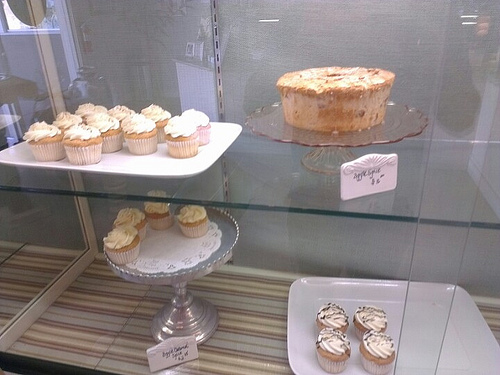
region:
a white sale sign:
[145, 331, 206, 373]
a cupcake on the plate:
[313, 299, 350, 335]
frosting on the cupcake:
[313, 325, 350, 355]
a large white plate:
[282, 267, 499, 373]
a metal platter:
[100, 200, 250, 352]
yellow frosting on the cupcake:
[175, 202, 209, 225]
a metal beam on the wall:
[208, 0, 237, 218]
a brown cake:
[270, 61, 400, 132]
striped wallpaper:
[0, 252, 499, 373]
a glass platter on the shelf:
[241, 97, 430, 179]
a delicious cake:
[171, 199, 212, 244]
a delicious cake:
[100, 222, 142, 267]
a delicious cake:
[141, 187, 172, 231]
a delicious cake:
[113, 203, 148, 240]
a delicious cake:
[314, 327, 352, 369]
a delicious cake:
[358, 325, 399, 373]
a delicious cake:
[274, 59, 401, 131]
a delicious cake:
[166, 113, 198, 156]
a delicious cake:
[123, 111, 157, 154]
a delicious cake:
[60, 118, 108, 161]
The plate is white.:
[261, 255, 498, 363]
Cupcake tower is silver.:
[85, 189, 234, 373]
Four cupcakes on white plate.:
[303, 292, 394, 374]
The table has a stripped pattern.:
[92, 262, 267, 373]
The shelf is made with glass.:
[65, 87, 498, 241]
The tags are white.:
[327, 149, 422, 206]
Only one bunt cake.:
[262, 48, 407, 148]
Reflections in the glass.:
[7, 33, 174, 108]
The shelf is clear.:
[42, 90, 490, 245]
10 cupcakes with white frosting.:
[58, 86, 250, 176]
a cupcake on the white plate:
[314, 327, 352, 374]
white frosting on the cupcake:
[315, 325, 350, 354]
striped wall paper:
[1, 254, 499, 374]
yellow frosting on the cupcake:
[98, 223, 147, 252]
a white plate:
[281, 265, 498, 374]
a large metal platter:
[99, 198, 245, 355]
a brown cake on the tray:
[270, 63, 397, 135]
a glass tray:
[236, 92, 431, 177]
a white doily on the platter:
[115, 212, 228, 274]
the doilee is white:
[145, 232, 219, 267]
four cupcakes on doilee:
[107, 205, 217, 272]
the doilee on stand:
[139, 225, 224, 337]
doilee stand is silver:
[138, 226, 235, 348]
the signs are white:
[143, 335, 192, 372]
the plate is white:
[285, 277, 480, 367]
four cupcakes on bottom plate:
[294, 285, 434, 365]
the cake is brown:
[272, 74, 413, 155]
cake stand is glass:
[267, 83, 418, 149]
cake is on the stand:
[270, 67, 405, 170]